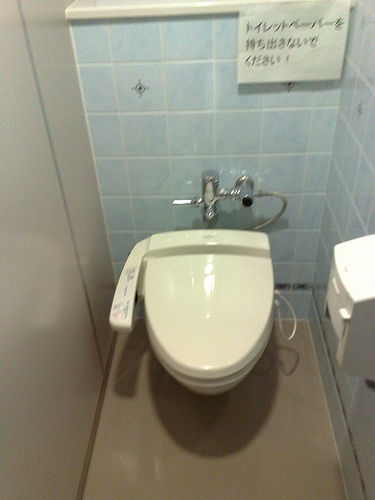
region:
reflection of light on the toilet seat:
[194, 262, 228, 304]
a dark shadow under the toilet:
[188, 414, 233, 449]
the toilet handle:
[165, 196, 195, 211]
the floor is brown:
[95, 462, 166, 488]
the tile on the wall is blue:
[218, 119, 282, 155]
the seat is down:
[148, 254, 269, 368]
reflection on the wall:
[31, 254, 78, 334]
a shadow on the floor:
[188, 405, 238, 446]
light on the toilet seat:
[197, 257, 225, 290]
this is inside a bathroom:
[17, 18, 326, 378]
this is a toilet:
[150, 258, 267, 345]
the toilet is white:
[139, 205, 263, 364]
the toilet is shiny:
[173, 268, 284, 341]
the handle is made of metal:
[157, 183, 251, 221]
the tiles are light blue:
[80, 70, 193, 166]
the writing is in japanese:
[229, 13, 326, 88]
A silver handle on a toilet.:
[170, 198, 201, 205]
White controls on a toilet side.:
[107, 238, 149, 332]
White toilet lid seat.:
[143, 256, 273, 372]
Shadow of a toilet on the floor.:
[113, 320, 281, 457]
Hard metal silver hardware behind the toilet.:
[172, 171, 253, 226]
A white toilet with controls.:
[109, 229, 274, 395]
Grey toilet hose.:
[251, 189, 287, 231]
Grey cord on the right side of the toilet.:
[273, 289, 297, 340]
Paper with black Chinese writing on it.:
[238, 1, 353, 84]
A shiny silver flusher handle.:
[171, 199, 199, 204]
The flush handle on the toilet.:
[171, 198, 202, 207]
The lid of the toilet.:
[147, 254, 266, 378]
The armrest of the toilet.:
[110, 256, 137, 332]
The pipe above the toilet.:
[256, 188, 286, 229]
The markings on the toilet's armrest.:
[109, 265, 130, 321]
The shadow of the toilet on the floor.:
[115, 321, 301, 460]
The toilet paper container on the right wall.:
[317, 228, 373, 378]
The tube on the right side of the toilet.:
[273, 289, 299, 340]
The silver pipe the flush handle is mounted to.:
[196, 169, 221, 226]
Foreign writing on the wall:
[231, 14, 348, 84]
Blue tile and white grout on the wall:
[87, 29, 331, 207]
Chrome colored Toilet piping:
[159, 167, 303, 234]